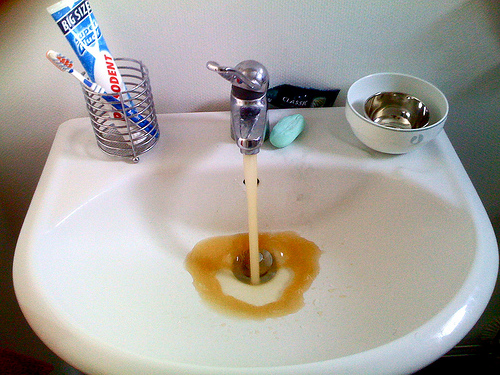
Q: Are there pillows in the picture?
A: No, there are no pillows.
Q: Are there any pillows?
A: No, there are no pillows.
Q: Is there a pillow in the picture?
A: No, there are no pillows.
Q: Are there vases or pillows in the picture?
A: No, there are no pillows or vases.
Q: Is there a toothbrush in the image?
A: Yes, there is a toothbrush.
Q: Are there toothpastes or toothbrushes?
A: Yes, there is a toothbrush.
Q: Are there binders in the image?
A: No, there are no binders.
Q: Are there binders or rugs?
A: No, there are no binders or rugs.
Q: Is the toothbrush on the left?
A: Yes, the toothbrush is on the left of the image.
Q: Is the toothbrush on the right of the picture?
A: No, the toothbrush is on the left of the image.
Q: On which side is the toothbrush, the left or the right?
A: The toothbrush is on the left of the image.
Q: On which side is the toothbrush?
A: The toothbrush is on the left of the image.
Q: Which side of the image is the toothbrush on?
A: The toothbrush is on the left of the image.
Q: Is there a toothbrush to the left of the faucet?
A: Yes, there is a toothbrush to the left of the faucet.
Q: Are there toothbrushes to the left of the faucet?
A: Yes, there is a toothbrush to the left of the faucet.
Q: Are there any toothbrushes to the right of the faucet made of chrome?
A: No, the toothbrush is to the left of the faucet.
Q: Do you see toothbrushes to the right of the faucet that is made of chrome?
A: No, the toothbrush is to the left of the faucet.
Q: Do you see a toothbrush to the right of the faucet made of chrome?
A: No, the toothbrush is to the left of the faucet.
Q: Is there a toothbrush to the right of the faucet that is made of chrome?
A: No, the toothbrush is to the left of the faucet.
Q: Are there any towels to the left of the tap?
A: No, there is a toothbrush to the left of the tap.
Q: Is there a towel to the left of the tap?
A: No, there is a toothbrush to the left of the tap.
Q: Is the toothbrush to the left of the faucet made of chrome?
A: Yes, the toothbrush is to the left of the tap.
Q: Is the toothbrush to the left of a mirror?
A: No, the toothbrush is to the left of the tap.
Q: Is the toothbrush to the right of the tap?
A: No, the toothbrush is to the left of the tap.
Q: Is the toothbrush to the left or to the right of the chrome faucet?
A: The toothbrush is to the left of the tap.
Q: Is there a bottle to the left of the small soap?
A: No, there is a toothbrush to the left of the soap.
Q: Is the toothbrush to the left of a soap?
A: Yes, the toothbrush is to the left of a soap.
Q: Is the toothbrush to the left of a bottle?
A: No, the toothbrush is to the left of a soap.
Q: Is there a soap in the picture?
A: Yes, there is a soap.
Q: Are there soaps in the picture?
A: Yes, there is a soap.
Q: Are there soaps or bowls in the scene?
A: Yes, there is a soap.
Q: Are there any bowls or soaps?
A: Yes, there is a soap.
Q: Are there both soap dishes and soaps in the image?
A: No, there is a soap but no soap dishes.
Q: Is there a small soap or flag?
A: Yes, there is a small soap.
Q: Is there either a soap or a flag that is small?
A: Yes, the soap is small.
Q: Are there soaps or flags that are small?
A: Yes, the soap is small.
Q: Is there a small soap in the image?
A: Yes, there is a small soap.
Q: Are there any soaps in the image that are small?
A: Yes, there is a soap that is small.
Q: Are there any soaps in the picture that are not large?
A: Yes, there is a small soap.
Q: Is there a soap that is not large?
A: Yes, there is a small soap.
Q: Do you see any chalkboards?
A: No, there are no chalkboards.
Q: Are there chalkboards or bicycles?
A: No, there are no chalkboards or bicycles.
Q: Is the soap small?
A: Yes, the soap is small.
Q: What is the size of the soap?
A: The soap is small.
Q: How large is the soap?
A: The soap is small.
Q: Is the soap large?
A: No, the soap is small.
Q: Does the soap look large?
A: No, the soap is small.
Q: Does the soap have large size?
A: No, the soap is small.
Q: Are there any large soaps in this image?
A: No, there is a soap but it is small.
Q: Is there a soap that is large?
A: No, there is a soap but it is small.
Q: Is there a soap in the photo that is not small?
A: No, there is a soap but it is small.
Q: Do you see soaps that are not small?
A: No, there is a soap but it is small.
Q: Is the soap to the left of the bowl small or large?
A: The soap is small.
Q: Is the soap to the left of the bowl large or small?
A: The soap is small.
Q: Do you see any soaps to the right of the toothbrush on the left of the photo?
A: Yes, there is a soap to the right of the toothbrush.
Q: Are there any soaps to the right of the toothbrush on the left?
A: Yes, there is a soap to the right of the toothbrush.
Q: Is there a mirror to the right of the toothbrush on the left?
A: No, there is a soap to the right of the toothbrush.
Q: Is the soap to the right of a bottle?
A: No, the soap is to the right of the toothbrush.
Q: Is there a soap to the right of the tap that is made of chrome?
A: Yes, there is a soap to the right of the tap.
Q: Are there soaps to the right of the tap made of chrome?
A: Yes, there is a soap to the right of the tap.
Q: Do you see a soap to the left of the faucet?
A: No, the soap is to the right of the faucet.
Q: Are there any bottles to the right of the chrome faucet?
A: No, there is a soap to the right of the faucet.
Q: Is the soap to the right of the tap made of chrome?
A: Yes, the soap is to the right of the faucet.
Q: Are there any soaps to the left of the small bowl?
A: Yes, there is a soap to the left of the bowl.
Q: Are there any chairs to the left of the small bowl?
A: No, there is a soap to the left of the bowl.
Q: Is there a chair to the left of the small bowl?
A: No, there is a soap to the left of the bowl.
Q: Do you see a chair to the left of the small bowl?
A: No, there is a soap to the left of the bowl.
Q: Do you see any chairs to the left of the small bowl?
A: No, there is a soap to the left of the bowl.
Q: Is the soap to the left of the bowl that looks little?
A: Yes, the soap is to the left of the bowl.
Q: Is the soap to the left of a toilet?
A: No, the soap is to the left of the bowl.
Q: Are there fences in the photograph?
A: No, there are no fences.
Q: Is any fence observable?
A: No, there are no fences.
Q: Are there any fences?
A: No, there are no fences.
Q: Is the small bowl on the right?
A: Yes, the bowl is on the right of the image.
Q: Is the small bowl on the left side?
A: No, the bowl is on the right of the image.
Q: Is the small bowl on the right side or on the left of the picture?
A: The bowl is on the right of the image.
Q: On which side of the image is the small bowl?
A: The bowl is on the right of the image.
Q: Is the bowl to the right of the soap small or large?
A: The bowl is small.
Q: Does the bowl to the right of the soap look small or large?
A: The bowl is small.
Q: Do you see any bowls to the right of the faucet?
A: Yes, there is a bowl to the right of the faucet.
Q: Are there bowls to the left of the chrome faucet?
A: No, the bowl is to the right of the faucet.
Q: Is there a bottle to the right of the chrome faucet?
A: No, there is a bowl to the right of the tap.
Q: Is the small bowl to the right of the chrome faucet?
A: Yes, the bowl is to the right of the tap.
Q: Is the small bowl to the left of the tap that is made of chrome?
A: No, the bowl is to the right of the tap.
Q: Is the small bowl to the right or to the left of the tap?
A: The bowl is to the right of the tap.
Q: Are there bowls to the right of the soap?
A: Yes, there is a bowl to the right of the soap.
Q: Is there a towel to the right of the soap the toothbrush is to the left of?
A: No, there is a bowl to the right of the soap.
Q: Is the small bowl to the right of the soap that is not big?
A: Yes, the bowl is to the right of the soap.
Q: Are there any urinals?
A: No, there are no urinals.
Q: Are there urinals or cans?
A: No, there are no urinals or cans.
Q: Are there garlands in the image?
A: No, there are no garlands.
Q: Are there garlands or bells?
A: No, there are no garlands or bells.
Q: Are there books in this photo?
A: No, there are no books.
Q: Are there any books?
A: No, there are no books.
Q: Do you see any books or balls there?
A: No, there are no books or balls.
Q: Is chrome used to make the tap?
A: Yes, the tap is made of chrome.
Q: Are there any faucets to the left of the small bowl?
A: Yes, there is a faucet to the left of the bowl.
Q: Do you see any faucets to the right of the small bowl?
A: No, the faucet is to the left of the bowl.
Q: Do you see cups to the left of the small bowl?
A: No, there is a faucet to the left of the bowl.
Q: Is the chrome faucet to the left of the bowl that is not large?
A: Yes, the faucet is to the left of the bowl.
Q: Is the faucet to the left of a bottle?
A: No, the faucet is to the left of the bowl.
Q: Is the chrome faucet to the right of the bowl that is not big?
A: No, the tap is to the left of the bowl.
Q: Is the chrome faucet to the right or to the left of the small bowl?
A: The tap is to the left of the bowl.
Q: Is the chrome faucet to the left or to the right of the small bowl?
A: The tap is to the left of the bowl.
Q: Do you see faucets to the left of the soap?
A: Yes, there is a faucet to the left of the soap.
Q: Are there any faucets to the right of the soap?
A: No, the faucet is to the left of the soap.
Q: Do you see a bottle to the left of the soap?
A: No, there is a faucet to the left of the soap.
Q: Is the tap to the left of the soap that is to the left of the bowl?
A: Yes, the tap is to the left of the soap.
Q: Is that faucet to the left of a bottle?
A: No, the faucet is to the left of the soap.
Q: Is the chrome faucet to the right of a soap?
A: No, the tap is to the left of a soap.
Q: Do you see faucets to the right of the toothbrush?
A: Yes, there is a faucet to the right of the toothbrush.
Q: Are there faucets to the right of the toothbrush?
A: Yes, there is a faucet to the right of the toothbrush.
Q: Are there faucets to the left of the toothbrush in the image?
A: No, the faucet is to the right of the toothbrush.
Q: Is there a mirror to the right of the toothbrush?
A: No, there is a faucet to the right of the toothbrush.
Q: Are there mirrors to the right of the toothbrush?
A: No, there is a faucet to the right of the toothbrush.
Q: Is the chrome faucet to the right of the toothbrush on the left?
A: Yes, the tap is to the right of the toothbrush.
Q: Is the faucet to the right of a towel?
A: No, the faucet is to the right of the toothbrush.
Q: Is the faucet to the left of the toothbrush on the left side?
A: No, the faucet is to the right of the toothbrush.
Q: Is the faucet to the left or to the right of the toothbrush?
A: The faucet is to the right of the toothbrush.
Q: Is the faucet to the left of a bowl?
A: Yes, the faucet is to the left of a bowl.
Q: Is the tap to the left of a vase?
A: No, the tap is to the left of a bowl.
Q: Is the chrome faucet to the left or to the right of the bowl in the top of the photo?
A: The tap is to the left of the bowl.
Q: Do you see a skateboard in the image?
A: No, there are no skateboards.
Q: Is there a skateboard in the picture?
A: No, there are no skateboards.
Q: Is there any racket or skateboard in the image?
A: No, there are no skateboards or rackets.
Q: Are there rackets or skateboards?
A: No, there are no skateboards or rackets.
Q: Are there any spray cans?
A: No, there are no spray cans.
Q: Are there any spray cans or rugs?
A: No, there are no spray cans or rugs.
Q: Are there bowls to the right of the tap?
A: Yes, there is a bowl to the right of the tap.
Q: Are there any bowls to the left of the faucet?
A: No, the bowl is to the right of the faucet.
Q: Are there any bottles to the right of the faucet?
A: No, there is a bowl to the right of the faucet.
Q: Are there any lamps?
A: No, there are no lamps.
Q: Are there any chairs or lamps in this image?
A: No, there are no lamps or chairs.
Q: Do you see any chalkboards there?
A: No, there are no chalkboards.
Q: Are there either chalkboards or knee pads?
A: No, there are no chalkboards or knee pads.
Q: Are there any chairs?
A: No, there are no chairs.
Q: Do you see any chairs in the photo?
A: No, there are no chairs.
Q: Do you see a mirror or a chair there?
A: No, there are no chairs or mirrors.